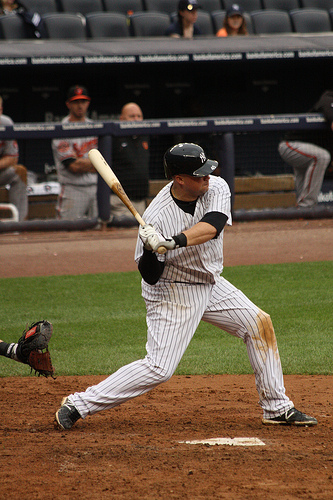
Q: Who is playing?
A: The Yankees?.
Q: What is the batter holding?
A: A baseball bat.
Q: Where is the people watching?
A: In the stands.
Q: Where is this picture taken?
A: A baseball stadium.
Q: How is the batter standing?
A: In a batter stance.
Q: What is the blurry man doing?
A: Watching.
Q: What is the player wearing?
A: Baseball uniform.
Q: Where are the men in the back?
A: Dugout.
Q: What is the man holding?
A: A bat.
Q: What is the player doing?
A: About to hit the ball.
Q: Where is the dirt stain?
A: Knee.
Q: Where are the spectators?
A: Bleachers.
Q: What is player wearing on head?
A: Helmet.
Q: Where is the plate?
A: In the dirt.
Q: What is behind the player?
A: Grass.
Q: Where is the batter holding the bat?
A: In his hands.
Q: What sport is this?
A: Baseball.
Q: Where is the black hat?
A: On the batter's head.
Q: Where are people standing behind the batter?
A: In the dugout?.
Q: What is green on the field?
A: Grass.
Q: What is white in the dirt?
A: Home plate.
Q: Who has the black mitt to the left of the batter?
A: Catcher.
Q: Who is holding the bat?
A: The batter.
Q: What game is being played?
A: Baseball.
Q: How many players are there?
A: Six.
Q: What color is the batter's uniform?
A: White with pinstripes.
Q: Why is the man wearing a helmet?
A: To protect his head.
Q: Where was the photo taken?
A: At a baseball field.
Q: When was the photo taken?
A: During a baseball game.